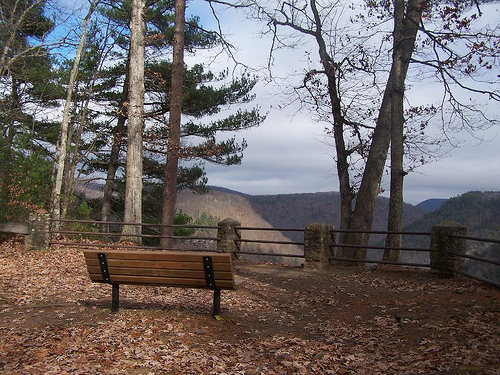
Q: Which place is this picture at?
A: It is at the park.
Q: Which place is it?
A: It is a park.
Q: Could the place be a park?
A: Yes, it is a park.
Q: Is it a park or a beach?
A: It is a park.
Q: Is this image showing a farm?
A: No, the picture is showing a park.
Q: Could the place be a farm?
A: No, it is a park.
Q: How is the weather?
A: It is cloudy.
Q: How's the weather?
A: It is cloudy.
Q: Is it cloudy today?
A: Yes, it is cloudy.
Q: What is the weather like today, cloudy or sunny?
A: It is cloudy.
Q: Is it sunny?
A: No, it is cloudy.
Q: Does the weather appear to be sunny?
A: No, it is cloudy.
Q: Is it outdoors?
A: Yes, it is outdoors.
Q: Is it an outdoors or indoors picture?
A: It is outdoors.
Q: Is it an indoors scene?
A: No, it is outdoors.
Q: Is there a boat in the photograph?
A: No, there are no boats.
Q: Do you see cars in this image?
A: No, there are no cars.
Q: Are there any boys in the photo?
A: No, there are no boys.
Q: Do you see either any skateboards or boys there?
A: No, there are no boys or skateboards.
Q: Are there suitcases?
A: No, there are no suitcases.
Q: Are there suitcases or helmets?
A: No, there are no suitcases or helmets.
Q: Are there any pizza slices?
A: No, there are no pizza slices.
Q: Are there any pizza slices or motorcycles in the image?
A: No, there are no pizza slices or motorcycles.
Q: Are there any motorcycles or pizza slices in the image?
A: No, there are no pizza slices or motorcycles.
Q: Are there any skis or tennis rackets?
A: No, there are no skis or tennis rackets.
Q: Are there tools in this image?
A: No, there are no tools.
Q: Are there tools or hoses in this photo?
A: No, there are no tools or hoses.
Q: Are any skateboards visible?
A: No, there are no skateboards.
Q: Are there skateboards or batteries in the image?
A: No, there are no skateboards or batteries.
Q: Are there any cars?
A: No, there are no cars.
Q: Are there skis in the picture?
A: No, there are no skis.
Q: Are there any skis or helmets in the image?
A: No, there are no skis or helmets.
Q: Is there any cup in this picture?
A: No, there are no cups.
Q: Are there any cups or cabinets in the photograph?
A: No, there are no cups or cabinets.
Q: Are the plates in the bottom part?
A: Yes, the plates are in the bottom of the image.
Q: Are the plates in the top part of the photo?
A: No, the plates are in the bottom of the image.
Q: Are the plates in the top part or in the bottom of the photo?
A: The plates are in the bottom of the image.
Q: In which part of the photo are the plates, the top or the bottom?
A: The plates are in the bottom of the image.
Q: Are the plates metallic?
A: Yes, the plates are metallic.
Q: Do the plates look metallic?
A: Yes, the plates are metallic.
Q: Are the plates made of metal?
A: Yes, the plates are made of metal.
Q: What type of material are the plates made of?
A: The plates are made of metal.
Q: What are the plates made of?
A: The plates are made of metal.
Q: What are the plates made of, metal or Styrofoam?
A: The plates are made of metal.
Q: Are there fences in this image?
A: Yes, there is a fence.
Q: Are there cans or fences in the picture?
A: Yes, there is a fence.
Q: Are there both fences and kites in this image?
A: No, there is a fence but no kites.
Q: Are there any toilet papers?
A: No, there are no toilet papers.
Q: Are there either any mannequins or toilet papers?
A: No, there are no toilet papers or mannequins.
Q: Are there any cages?
A: No, there are no cages.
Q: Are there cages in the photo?
A: No, there are no cages.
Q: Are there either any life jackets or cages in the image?
A: No, there are no cages or life jackets.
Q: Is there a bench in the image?
A: Yes, there is a bench.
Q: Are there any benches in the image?
A: Yes, there is a bench.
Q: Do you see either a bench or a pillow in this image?
A: Yes, there is a bench.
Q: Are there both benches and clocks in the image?
A: No, there is a bench but no clocks.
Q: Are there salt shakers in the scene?
A: No, there are no salt shakers.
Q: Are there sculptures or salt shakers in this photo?
A: No, there are no salt shakers or sculptures.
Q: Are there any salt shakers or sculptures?
A: No, there are no salt shakers or sculptures.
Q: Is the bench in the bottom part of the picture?
A: Yes, the bench is in the bottom of the image.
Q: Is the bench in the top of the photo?
A: No, the bench is in the bottom of the image.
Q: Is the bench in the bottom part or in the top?
A: The bench is in the bottom of the image.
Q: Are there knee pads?
A: No, there are no knee pads.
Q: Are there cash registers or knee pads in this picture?
A: No, there are no knee pads or cash registers.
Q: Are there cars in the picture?
A: No, there are no cars.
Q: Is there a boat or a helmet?
A: No, there are no helmets or boats.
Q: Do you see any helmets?
A: No, there are no helmets.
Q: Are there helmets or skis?
A: No, there are no helmets or skis.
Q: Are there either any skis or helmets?
A: No, there are no helmets or skis.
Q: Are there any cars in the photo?
A: No, there are no cars.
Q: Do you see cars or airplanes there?
A: No, there are no cars or airplanes.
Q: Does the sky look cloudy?
A: Yes, the sky is cloudy.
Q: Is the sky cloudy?
A: Yes, the sky is cloudy.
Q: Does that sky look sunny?
A: No, the sky is cloudy.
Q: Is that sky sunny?
A: No, the sky is cloudy.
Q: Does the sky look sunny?
A: No, the sky is cloudy.